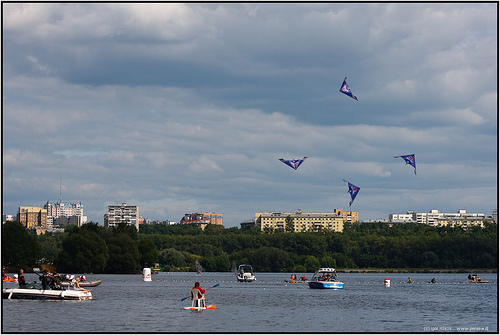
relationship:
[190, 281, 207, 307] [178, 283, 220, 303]
person holding oar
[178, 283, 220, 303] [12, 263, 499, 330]
oar on water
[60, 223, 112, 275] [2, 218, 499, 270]
tree by lake shore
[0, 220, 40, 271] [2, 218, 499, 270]
tree by lake shore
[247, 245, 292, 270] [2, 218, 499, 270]
tree by lake shore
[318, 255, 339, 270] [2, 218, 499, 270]
tree by lake shore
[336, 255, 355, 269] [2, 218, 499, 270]
tree by lake shore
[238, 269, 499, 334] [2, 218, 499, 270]
lake by lake shore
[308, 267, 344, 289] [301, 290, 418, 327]
boat on water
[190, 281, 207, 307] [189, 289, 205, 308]
person in chair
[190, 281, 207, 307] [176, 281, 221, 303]
person with oar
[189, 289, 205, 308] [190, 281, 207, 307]
chair with person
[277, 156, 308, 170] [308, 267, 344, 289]
kite flying above boat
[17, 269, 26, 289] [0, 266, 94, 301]
boater on boat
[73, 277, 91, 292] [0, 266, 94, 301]
person on boat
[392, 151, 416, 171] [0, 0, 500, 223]
kites flying in skies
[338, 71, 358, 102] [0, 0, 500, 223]
kites flying in skies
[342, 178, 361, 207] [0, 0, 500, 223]
kite flying in skies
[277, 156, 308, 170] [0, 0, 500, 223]
kite flying in skies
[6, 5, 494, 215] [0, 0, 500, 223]
clouds in skies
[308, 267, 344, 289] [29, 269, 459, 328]
boat in water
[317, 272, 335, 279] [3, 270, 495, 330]
boater floating on water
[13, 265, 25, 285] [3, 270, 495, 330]
boater floating on water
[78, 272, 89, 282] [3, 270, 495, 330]
boater floating on water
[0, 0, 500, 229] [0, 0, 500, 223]
clouds covering skies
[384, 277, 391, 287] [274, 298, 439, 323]
barrier in water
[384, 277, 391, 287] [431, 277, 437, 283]
barrier next to person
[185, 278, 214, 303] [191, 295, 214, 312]
person on chair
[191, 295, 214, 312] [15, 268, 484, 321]
chair on water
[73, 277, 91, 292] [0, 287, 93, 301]
person on boat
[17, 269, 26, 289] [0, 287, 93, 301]
boater on boat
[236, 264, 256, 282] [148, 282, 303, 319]
boat on water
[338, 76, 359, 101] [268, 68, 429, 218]
kites in bunch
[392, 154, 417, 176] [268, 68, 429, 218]
kites in bunch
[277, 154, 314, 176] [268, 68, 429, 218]
kite in bunch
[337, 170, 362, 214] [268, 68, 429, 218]
kite in bunch